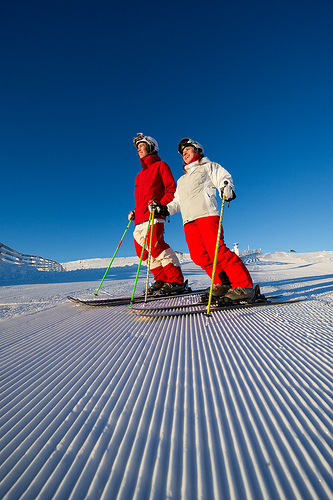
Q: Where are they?
A: Slopes.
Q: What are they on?
A: Snow.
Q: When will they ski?
A: Soon.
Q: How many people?
A: 2.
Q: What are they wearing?
A: Jackets.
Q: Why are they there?
A: To ski.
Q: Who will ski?
A: People.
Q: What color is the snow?
A: White.